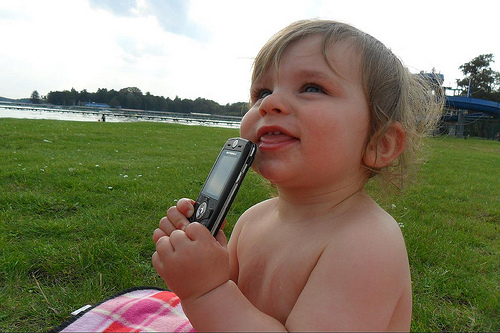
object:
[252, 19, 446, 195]
hair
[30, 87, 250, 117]
trees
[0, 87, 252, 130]
distance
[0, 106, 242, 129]
water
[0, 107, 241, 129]
front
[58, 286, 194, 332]
blanket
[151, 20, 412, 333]
child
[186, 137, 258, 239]
phone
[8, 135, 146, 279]
grass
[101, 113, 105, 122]
person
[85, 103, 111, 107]
roof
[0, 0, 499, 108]
sky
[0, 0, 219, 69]
clouds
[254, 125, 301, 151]
mouth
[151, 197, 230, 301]
hands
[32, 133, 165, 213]
flowers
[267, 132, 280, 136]
teeth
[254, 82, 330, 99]
eyes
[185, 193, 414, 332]
no shirt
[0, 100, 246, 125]
line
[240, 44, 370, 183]
up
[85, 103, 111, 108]
house